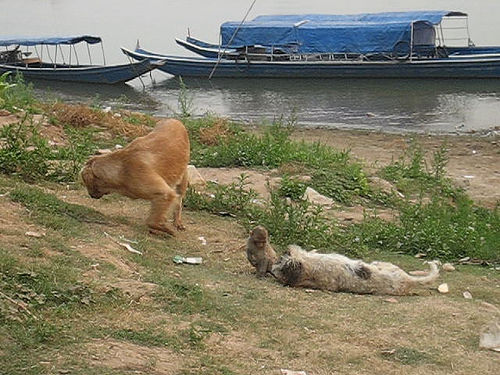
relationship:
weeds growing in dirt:
[198, 176, 332, 235] [260, 129, 480, 231]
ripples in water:
[243, 103, 382, 123] [215, 85, 392, 125]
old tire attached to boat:
[388, 38, 414, 65] [143, 13, 484, 113]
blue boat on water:
[9, 28, 153, 82] [211, 72, 484, 138]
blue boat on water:
[9, 28, 153, 82] [267, 84, 472, 129]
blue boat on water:
[9, 28, 153, 82] [305, 90, 484, 134]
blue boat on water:
[9, 28, 153, 82] [286, 83, 485, 143]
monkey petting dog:
[257, 117, 470, 317] [279, 230, 483, 313]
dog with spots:
[238, 224, 436, 295] [290, 240, 403, 287]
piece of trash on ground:
[174, 249, 207, 268] [91, 208, 240, 291]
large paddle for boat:
[118, 55, 151, 89] [128, 24, 484, 115]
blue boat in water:
[0, 35, 153, 82] [200, 81, 455, 128]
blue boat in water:
[0, 35, 153, 82] [251, 82, 481, 147]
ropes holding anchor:
[205, 1, 273, 65] [120, 32, 171, 89]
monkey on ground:
[257, 117, 470, 317] [228, 157, 393, 258]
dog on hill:
[88, 112, 205, 253] [25, 138, 447, 372]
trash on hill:
[25, 230, 51, 243] [8, 112, 304, 372]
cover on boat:
[219, 18, 421, 57] [2, 50, 217, 86]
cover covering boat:
[219, 18, 421, 57] [35, 56, 170, 84]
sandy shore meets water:
[185, 109, 499, 150] [230, 84, 378, 124]